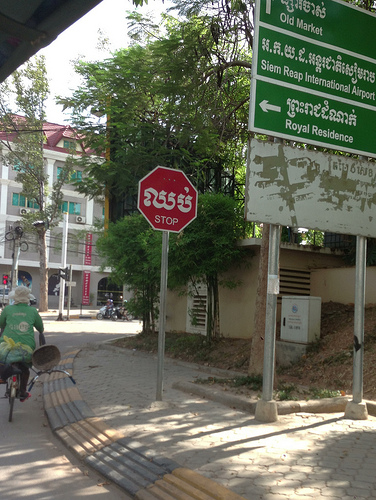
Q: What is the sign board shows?
A: Stop.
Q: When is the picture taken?
A: Daytime.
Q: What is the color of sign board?
A: Red and white.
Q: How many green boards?
A: 3.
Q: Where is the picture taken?
A: On the street.